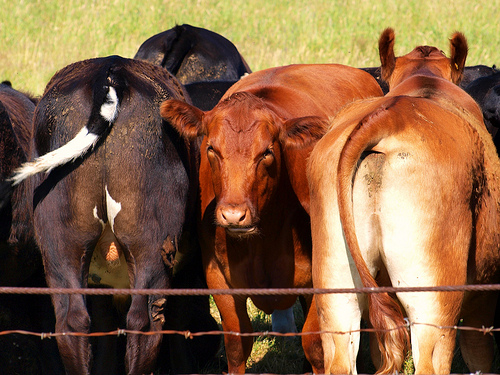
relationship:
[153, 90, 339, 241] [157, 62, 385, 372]
face of cow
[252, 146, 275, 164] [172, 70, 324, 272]
eye of cow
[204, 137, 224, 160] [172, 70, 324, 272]
eye of cow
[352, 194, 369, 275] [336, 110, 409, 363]
side of tail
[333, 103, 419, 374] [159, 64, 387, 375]
tail of brown cow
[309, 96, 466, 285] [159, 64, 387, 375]
brown butt of brown cow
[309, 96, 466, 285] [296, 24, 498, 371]
brown butt of brown cow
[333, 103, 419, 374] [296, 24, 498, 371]
tail on brown cow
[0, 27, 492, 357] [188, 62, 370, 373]
herd of cows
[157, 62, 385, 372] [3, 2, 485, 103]
cow chewing grass